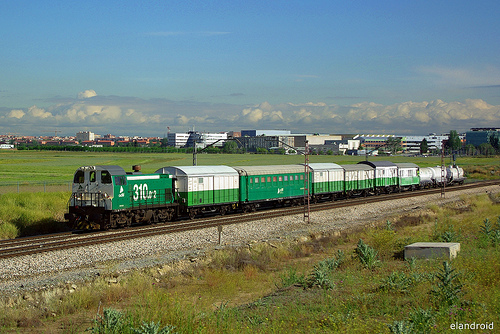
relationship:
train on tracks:
[53, 149, 471, 236] [30, 232, 79, 259]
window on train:
[99, 167, 111, 184] [61, 150, 465, 230]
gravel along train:
[18, 280, 26, 289] [52, 135, 481, 234]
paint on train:
[319, 171, 326, 173] [61, 150, 465, 230]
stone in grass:
[403, 238, 463, 263] [0, 194, 498, 329]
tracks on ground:
[0, 180, 497, 257] [0, 147, 498, 332]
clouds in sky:
[0, 91, 498, 134] [0, 2, 498, 117]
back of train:
[74, 169, 116, 215] [398, 164, 457, 184]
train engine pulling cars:
[63, 161, 173, 222] [80, 141, 447, 207]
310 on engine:
[131, 179, 153, 201] [69, 153, 171, 218]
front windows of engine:
[74, 166, 110, 181] [62, 158, 178, 225]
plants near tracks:
[353, 240, 381, 269] [2, 167, 497, 250]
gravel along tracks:
[5, 185, 491, 290] [0, 180, 497, 257]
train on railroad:
[63, 160, 464, 231] [1, 178, 497, 255]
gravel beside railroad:
[5, 185, 491, 290] [88, 114, 476, 284]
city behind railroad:
[3, 116, 498, 156] [10, 144, 267, 308]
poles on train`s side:
[302, 138, 312, 222] [108, 168, 436, 226]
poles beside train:
[437, 141, 449, 204] [58, 152, 470, 217]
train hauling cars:
[63, 160, 464, 231] [179, 157, 428, 221]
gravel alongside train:
[18, 280, 26, 289] [47, 115, 469, 245]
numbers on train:
[128, 183, 156, 200] [66, 155, 200, 232]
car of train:
[236, 149, 309, 190] [63, 160, 464, 231]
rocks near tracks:
[61, 249, 158, 261] [3, 174, 484, 259]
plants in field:
[355, 240, 383, 270] [6, 190, 484, 326]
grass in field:
[20, 188, 493, 331] [3, 150, 493, 328]